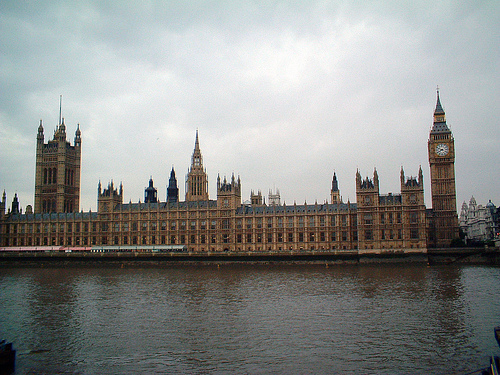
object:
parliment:
[4, 82, 462, 254]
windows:
[121, 221, 130, 232]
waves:
[91, 282, 209, 309]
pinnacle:
[433, 84, 447, 114]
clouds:
[118, 34, 217, 97]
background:
[141, 163, 430, 203]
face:
[437, 146, 447, 155]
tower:
[34, 94, 82, 246]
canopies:
[468, 210, 476, 213]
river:
[2, 268, 496, 371]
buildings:
[455, 195, 497, 244]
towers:
[35, 94, 83, 209]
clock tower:
[428, 85, 459, 246]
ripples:
[221, 327, 322, 350]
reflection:
[434, 263, 470, 346]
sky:
[1, 0, 496, 192]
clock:
[435, 145, 449, 157]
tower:
[426, 85, 461, 249]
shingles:
[149, 202, 159, 212]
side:
[99, 172, 240, 247]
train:
[91, 245, 187, 252]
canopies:
[1, 242, 185, 254]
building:
[1, 83, 458, 257]